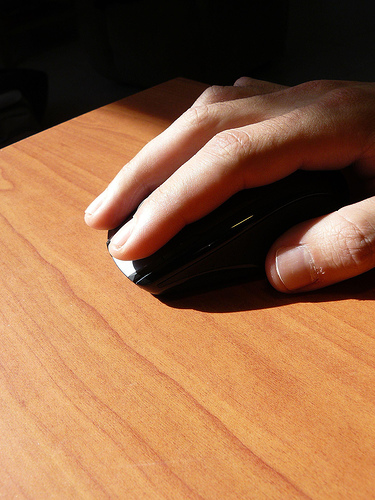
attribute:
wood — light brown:
[0, 74, 374, 499]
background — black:
[0, 0, 373, 148]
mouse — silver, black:
[104, 172, 360, 297]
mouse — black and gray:
[174, 223, 265, 283]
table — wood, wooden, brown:
[1, 68, 373, 499]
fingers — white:
[77, 90, 349, 264]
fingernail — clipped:
[275, 246, 316, 289]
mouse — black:
[103, 157, 351, 292]